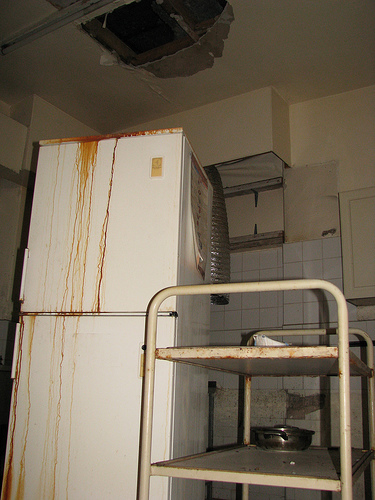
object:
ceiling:
[0, 0, 374, 125]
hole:
[80, 1, 234, 78]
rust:
[72, 138, 97, 205]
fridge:
[4, 127, 213, 499]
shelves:
[138, 277, 375, 499]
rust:
[177, 351, 223, 361]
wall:
[241, 238, 345, 283]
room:
[0, 0, 373, 499]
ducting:
[200, 165, 231, 307]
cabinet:
[338, 183, 374, 306]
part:
[316, 64, 324, 72]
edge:
[160, 347, 336, 350]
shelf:
[157, 342, 369, 376]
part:
[175, 468, 180, 475]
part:
[272, 439, 275, 448]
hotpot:
[252, 420, 315, 449]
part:
[347, 114, 356, 132]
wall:
[289, 81, 374, 182]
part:
[122, 211, 138, 232]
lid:
[254, 422, 315, 436]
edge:
[325, 91, 356, 100]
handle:
[256, 425, 287, 441]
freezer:
[7, 134, 215, 499]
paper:
[190, 155, 212, 281]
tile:
[303, 238, 322, 260]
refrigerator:
[2, 128, 229, 499]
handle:
[9, 321, 22, 379]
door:
[1, 315, 178, 497]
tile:
[301, 259, 324, 278]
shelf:
[149, 442, 341, 492]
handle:
[18, 245, 30, 302]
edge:
[124, 127, 174, 136]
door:
[20, 134, 181, 315]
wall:
[189, 85, 274, 154]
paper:
[251, 334, 295, 348]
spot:
[101, 53, 115, 71]